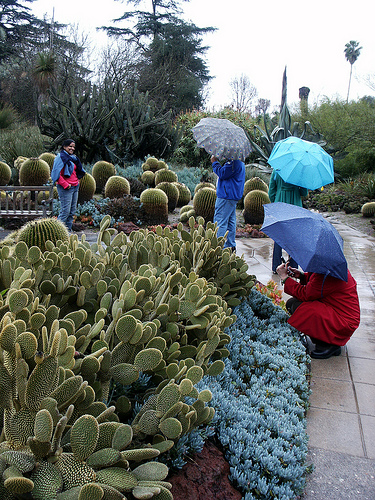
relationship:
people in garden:
[41, 110, 362, 382] [19, 183, 303, 380]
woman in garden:
[275, 250, 361, 362] [1, 207, 314, 498]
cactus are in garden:
[41, 334, 132, 416] [12, 289, 294, 499]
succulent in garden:
[164, 286, 323, 497] [12, 289, 294, 499]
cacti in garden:
[16, 302, 94, 383] [12, 289, 294, 499]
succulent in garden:
[233, 349, 285, 430] [12, 289, 294, 499]